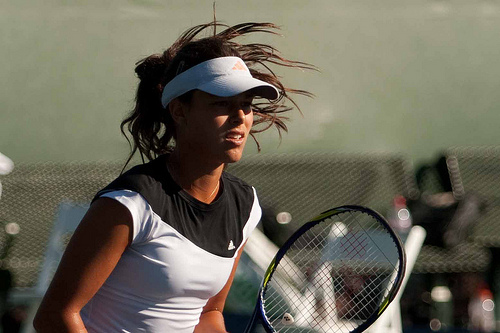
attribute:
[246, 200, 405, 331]
racket — black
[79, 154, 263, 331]
shirt — black and white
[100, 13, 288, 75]
hair — brown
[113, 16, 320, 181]
hair — long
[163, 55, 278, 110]
visor — white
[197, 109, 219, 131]
light skinned — player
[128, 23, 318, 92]
hair — wavy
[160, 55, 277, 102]
cap — white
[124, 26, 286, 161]
hair — long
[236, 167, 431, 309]
racket — big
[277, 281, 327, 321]
dampener — small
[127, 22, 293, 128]
hair — brown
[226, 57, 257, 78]
symbol — orange